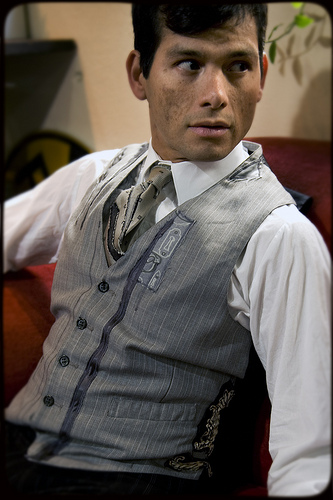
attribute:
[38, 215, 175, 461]
line — large, blue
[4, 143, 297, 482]
vest — tan, blue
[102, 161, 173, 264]
tie — gold, gray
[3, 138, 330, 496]
t shirt — long sleeve, white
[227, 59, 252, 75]
eyes — dark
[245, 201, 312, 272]
sleeve — White long 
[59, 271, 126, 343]
buttons — BLACK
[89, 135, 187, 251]
tie — mans 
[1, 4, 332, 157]
wall — pinkish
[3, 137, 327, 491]
furniture — red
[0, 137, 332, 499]
shirt — dress shirt, white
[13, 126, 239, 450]
front — button-down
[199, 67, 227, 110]
nose — aquiline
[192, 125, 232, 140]
lip — wide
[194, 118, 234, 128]
lip — wide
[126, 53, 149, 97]
ear — large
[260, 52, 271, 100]
ear — large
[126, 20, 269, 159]
skin — damaged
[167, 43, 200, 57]
brow — medium sized, short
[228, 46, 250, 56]
brow — short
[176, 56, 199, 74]
eye — wary, looking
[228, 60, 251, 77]
eye — wary, looking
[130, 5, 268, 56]
hair — black, sweeping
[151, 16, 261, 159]
face — caucasian, angled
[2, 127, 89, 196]
object — round, yellow, black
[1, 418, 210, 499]
pants — black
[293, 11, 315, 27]
leaves — green